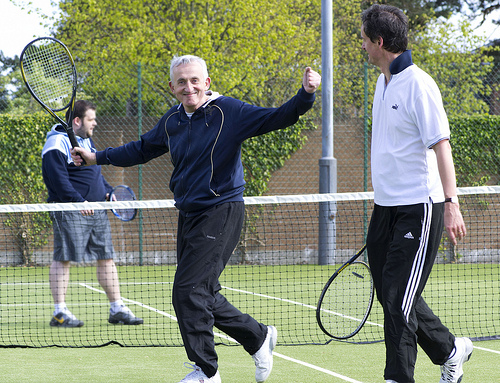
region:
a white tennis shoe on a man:
[253, 318, 288, 379]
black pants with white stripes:
[357, 197, 454, 377]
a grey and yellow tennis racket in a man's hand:
[17, 32, 87, 164]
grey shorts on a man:
[42, 200, 112, 260]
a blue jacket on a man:
[90, 75, 320, 216]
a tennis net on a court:
[0, 180, 495, 345]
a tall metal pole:
[313, 2, 345, 261]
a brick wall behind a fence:
[1, 118, 496, 259]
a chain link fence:
[0, 62, 497, 259]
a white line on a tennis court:
[92, 286, 360, 382]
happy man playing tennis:
[1, 25, 343, 382]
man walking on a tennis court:
[291, 9, 496, 378]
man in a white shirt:
[313, 2, 488, 382]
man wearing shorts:
[12, 92, 165, 334]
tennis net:
[1, 180, 498, 353]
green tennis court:
[3, 253, 498, 381]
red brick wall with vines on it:
[1, 112, 498, 276]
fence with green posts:
[3, 55, 496, 264]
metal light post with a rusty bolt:
[285, 0, 350, 269]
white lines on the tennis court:
[3, 270, 495, 381]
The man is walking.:
[313, 4, 481, 380]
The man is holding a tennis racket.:
[303, 4, 488, 378]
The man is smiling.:
[13, 21, 329, 381]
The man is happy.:
[13, 35, 327, 381]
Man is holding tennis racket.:
[8, 31, 322, 381]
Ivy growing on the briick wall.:
[3, 105, 498, 262]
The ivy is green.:
[3, 108, 498, 254]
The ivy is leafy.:
[0, 105, 499, 270]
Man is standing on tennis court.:
[31, 96, 162, 362]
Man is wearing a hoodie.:
[15, 85, 150, 341]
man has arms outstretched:
[96, 51, 331, 371]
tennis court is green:
[17, 248, 374, 369]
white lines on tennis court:
[15, 258, 331, 375]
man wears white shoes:
[185, 324, 277, 381]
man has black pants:
[134, 181, 301, 372]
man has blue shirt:
[140, 98, 248, 191]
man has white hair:
[165, 58, 209, 95]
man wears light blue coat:
[47, 125, 117, 211]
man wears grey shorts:
[25, 207, 142, 266]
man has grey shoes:
[35, 291, 140, 338]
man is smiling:
[171, 50, 236, 112]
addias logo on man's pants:
[390, 212, 424, 257]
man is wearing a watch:
[418, 179, 460, 208]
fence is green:
[84, 46, 199, 160]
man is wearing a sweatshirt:
[27, 105, 120, 240]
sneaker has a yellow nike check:
[42, 307, 92, 330]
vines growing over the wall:
[255, 103, 353, 241]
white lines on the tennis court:
[214, 282, 372, 381]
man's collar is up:
[355, 33, 436, 90]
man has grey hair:
[139, 45, 241, 87]